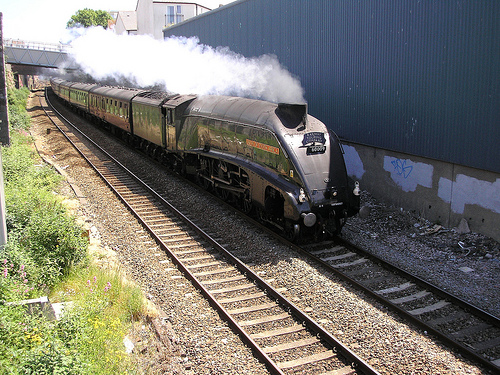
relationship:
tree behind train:
[67, 6, 110, 31] [50, 75, 361, 247]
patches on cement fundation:
[343, 142, 498, 215] [341, 139, 498, 240]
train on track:
[50, 75, 361, 247] [41, 85, 499, 374]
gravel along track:
[31, 89, 496, 374] [41, 85, 500, 375]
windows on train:
[52, 77, 172, 135] [50, 75, 361, 247]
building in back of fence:
[132, 1, 211, 39] [162, 3, 497, 173]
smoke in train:
[67, 22, 319, 114] [50, 75, 361, 247]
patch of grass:
[0, 231, 156, 375] [1, 93, 161, 373]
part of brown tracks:
[373, 276, 459, 333] [156, 241, 269, 301]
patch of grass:
[3, 231, 155, 371] [8, 92, 26, 127]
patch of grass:
[3, 231, 155, 371] [3, 147, 46, 200]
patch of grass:
[3, 231, 155, 371] [8, 180, 75, 272]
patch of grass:
[3, 231, 155, 371] [52, 286, 120, 373]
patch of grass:
[0, 231, 156, 375] [7, 320, 56, 354]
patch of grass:
[0, 231, 156, 375] [0, 85, 137, 373]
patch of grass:
[0, 231, 156, 375] [68, 277, 142, 342]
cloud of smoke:
[51, 20, 311, 105] [59, 26, 309, 106]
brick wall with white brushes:
[366, 117, 491, 205] [391, 101, 430, 131]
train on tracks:
[50, 75, 361, 247] [15, 69, 499, 374]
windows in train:
[52, 77, 136, 135] [50, 75, 361, 247]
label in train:
[239, 131, 285, 160] [50, 75, 361, 247]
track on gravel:
[41, 85, 500, 375] [278, 290, 413, 364]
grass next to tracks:
[40, 266, 80, 294] [154, 239, 337, 358]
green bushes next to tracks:
[0, 86, 146, 374] [154, 239, 337, 358]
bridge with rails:
[2, 38, 72, 68] [3, 37, 72, 55]